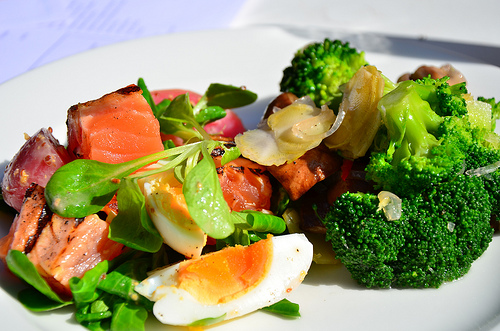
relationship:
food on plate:
[87, 92, 464, 269] [2, 26, 499, 328]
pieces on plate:
[3, 127, 64, 209] [2, 26, 499, 328]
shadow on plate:
[303, 262, 355, 285] [172, 33, 278, 85]